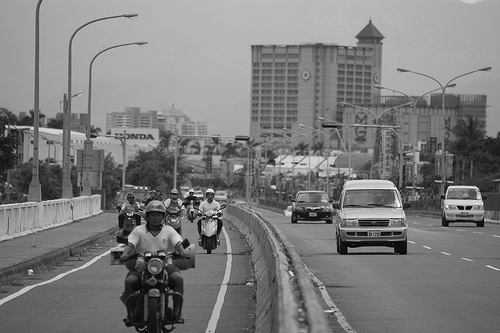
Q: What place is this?
A: It is a street.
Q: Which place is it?
A: It is a street.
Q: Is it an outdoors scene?
A: Yes, it is outdoors.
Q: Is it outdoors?
A: Yes, it is outdoors.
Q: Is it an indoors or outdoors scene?
A: It is outdoors.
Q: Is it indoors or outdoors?
A: It is outdoors.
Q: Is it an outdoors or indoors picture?
A: It is outdoors.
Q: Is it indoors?
A: No, it is outdoors.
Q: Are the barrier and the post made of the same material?
A: No, the barrier is made of cement and the post is made of metal.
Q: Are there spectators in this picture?
A: No, there are no spectators.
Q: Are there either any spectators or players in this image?
A: No, there are no spectators or players.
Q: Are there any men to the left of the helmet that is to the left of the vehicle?
A: Yes, there is a man to the left of the helmet.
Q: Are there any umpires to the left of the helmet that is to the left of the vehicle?
A: No, there is a man to the left of the helmet.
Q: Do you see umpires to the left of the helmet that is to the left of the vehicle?
A: No, there is a man to the left of the helmet.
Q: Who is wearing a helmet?
A: The man is wearing a helmet.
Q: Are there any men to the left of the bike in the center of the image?
A: Yes, there is a man to the left of the bike.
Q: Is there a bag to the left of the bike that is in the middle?
A: No, there is a man to the left of the bike.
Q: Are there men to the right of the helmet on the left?
A: Yes, there is a man to the right of the helmet.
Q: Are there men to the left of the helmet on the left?
A: No, the man is to the right of the helmet.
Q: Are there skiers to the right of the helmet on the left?
A: No, there is a man to the right of the helmet.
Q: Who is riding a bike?
A: The man is riding a bike.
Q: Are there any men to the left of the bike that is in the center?
A: Yes, there is a man to the left of the bike.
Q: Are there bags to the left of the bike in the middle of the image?
A: No, there is a man to the left of the bike.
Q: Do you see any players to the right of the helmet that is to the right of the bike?
A: No, there is a man to the right of the helmet.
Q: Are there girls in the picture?
A: No, there are no girls.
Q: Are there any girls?
A: No, there are no girls.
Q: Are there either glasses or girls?
A: No, there are no girls or glasses.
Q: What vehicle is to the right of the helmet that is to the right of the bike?
A: The vehicle is a car.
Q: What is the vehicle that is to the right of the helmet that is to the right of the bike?
A: The vehicle is a car.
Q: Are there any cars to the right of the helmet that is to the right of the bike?
A: Yes, there is a car to the right of the helmet.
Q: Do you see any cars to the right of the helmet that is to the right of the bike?
A: Yes, there is a car to the right of the helmet.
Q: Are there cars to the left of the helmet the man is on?
A: No, the car is to the right of the helmet.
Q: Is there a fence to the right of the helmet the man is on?
A: No, there is a car to the right of the helmet.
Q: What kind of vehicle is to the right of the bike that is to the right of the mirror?
A: The vehicle is a car.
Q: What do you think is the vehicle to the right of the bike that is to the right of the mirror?
A: The vehicle is a car.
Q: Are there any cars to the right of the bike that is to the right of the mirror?
A: Yes, there is a car to the right of the bike.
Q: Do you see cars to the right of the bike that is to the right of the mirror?
A: Yes, there is a car to the right of the bike.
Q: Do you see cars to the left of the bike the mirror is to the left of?
A: No, the car is to the right of the bike.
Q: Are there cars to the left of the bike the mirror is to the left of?
A: No, the car is to the right of the bike.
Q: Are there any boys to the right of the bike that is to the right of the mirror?
A: No, there is a car to the right of the bike.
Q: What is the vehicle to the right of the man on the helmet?
A: The vehicle is a car.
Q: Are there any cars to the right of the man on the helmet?
A: Yes, there is a car to the right of the man.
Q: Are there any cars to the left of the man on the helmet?
A: No, the car is to the right of the man.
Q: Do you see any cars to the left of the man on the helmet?
A: No, the car is to the right of the man.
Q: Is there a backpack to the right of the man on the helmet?
A: No, there is a car to the right of the man.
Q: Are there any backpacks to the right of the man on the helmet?
A: No, there is a car to the right of the man.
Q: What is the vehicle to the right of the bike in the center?
A: The vehicle is a car.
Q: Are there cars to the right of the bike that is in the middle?
A: Yes, there is a car to the right of the bike.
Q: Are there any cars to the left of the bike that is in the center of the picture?
A: No, the car is to the right of the bike.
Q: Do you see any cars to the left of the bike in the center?
A: No, the car is to the right of the bike.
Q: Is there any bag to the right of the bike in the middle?
A: No, there is a car to the right of the bike.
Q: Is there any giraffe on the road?
A: No, there is a car on the road.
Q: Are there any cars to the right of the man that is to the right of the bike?
A: Yes, there is a car to the right of the man.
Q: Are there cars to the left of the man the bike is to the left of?
A: No, the car is to the right of the man.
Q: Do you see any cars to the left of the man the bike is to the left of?
A: No, the car is to the right of the man.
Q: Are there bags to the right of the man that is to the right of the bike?
A: No, there is a car to the right of the man.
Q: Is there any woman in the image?
A: No, there are no women.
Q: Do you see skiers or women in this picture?
A: No, there are no women or skiers.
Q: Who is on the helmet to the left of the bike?
A: The man is on the helmet.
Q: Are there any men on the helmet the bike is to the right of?
A: Yes, there is a man on the helmet.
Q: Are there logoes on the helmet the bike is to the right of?
A: No, there is a man on the helmet.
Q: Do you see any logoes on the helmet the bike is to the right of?
A: No, there is a man on the helmet.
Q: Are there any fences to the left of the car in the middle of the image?
A: No, there is a man to the left of the car.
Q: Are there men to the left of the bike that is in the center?
A: Yes, there is a man to the left of the bike.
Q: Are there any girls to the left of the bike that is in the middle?
A: No, there is a man to the left of the bike.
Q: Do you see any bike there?
A: Yes, there is a bike.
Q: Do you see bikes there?
A: Yes, there is a bike.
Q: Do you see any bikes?
A: Yes, there is a bike.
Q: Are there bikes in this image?
A: Yes, there is a bike.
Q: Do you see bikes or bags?
A: Yes, there is a bike.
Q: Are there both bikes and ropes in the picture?
A: No, there is a bike but no ropes.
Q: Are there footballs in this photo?
A: No, there are no footballs.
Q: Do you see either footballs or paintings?
A: No, there are no footballs or paintings.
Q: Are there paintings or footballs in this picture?
A: No, there are no footballs or paintings.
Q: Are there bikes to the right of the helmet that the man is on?
A: Yes, there is a bike to the right of the helmet.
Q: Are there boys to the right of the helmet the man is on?
A: No, there is a bike to the right of the helmet.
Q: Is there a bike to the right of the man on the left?
A: Yes, there is a bike to the right of the man.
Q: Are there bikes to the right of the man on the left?
A: Yes, there is a bike to the right of the man.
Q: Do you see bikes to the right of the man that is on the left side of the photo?
A: Yes, there is a bike to the right of the man.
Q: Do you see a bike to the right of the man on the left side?
A: Yes, there is a bike to the right of the man.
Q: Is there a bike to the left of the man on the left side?
A: No, the bike is to the right of the man.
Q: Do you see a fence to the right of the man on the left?
A: No, there is a bike to the right of the man.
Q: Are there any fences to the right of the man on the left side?
A: No, there is a bike to the right of the man.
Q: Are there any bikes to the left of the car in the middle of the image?
A: Yes, there is a bike to the left of the car.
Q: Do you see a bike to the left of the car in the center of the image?
A: Yes, there is a bike to the left of the car.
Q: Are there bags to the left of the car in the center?
A: No, there is a bike to the left of the car.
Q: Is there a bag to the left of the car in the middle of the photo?
A: No, there is a bike to the left of the car.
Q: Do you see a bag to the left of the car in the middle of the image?
A: No, there is a bike to the left of the car.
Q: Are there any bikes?
A: Yes, there is a bike.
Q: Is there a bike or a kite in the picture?
A: Yes, there is a bike.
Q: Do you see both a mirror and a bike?
A: Yes, there are both a bike and a mirror.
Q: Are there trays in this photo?
A: No, there are no trays.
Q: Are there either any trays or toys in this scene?
A: No, there are no trays or toys.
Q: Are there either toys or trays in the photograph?
A: No, there are no trays or toys.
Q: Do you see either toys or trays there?
A: No, there are no trays or toys.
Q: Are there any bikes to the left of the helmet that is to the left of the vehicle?
A: Yes, there is a bike to the left of the helmet.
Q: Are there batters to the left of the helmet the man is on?
A: No, there is a bike to the left of the helmet.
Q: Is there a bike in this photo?
A: Yes, there is a bike.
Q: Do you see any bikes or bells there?
A: Yes, there is a bike.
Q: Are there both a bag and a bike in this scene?
A: No, there is a bike but no bags.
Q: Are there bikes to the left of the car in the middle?
A: Yes, there is a bike to the left of the car.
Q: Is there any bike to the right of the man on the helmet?
A: Yes, there is a bike to the right of the man.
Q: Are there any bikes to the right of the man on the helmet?
A: Yes, there is a bike to the right of the man.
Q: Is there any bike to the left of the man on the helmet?
A: No, the bike is to the right of the man.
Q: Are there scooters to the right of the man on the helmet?
A: No, there is a bike to the right of the man.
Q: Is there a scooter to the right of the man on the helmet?
A: No, there is a bike to the right of the man.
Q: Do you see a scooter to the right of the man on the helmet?
A: No, there is a bike to the right of the man.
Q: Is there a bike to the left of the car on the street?
A: Yes, there is a bike to the left of the car.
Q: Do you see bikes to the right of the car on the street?
A: No, the bike is to the left of the car.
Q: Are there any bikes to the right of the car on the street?
A: No, the bike is to the left of the car.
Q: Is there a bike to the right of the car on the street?
A: No, the bike is to the left of the car.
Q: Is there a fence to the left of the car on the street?
A: No, there is a bike to the left of the car.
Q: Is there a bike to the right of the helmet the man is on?
A: Yes, there is a bike to the right of the helmet.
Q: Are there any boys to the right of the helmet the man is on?
A: No, there is a bike to the right of the helmet.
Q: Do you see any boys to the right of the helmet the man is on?
A: No, there is a bike to the right of the helmet.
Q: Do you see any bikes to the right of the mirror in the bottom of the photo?
A: Yes, there is a bike to the right of the mirror.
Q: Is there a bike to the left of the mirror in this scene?
A: No, the bike is to the right of the mirror.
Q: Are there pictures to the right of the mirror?
A: No, there is a bike to the right of the mirror.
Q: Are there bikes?
A: Yes, there is a bike.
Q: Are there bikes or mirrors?
A: Yes, there is a bike.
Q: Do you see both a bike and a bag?
A: No, there is a bike but no bags.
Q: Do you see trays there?
A: No, there are no trays.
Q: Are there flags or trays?
A: No, there are no trays or flags.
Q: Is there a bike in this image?
A: Yes, there is a bike.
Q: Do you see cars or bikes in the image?
A: Yes, there is a bike.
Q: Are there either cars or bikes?
A: Yes, there is a bike.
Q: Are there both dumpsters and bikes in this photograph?
A: No, there is a bike but no dumpsters.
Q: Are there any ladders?
A: No, there are no ladders.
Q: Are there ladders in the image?
A: No, there are no ladders.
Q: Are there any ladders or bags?
A: No, there are no ladders or bags.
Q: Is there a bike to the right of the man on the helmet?
A: Yes, there is a bike to the right of the man.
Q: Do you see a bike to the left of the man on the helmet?
A: No, the bike is to the right of the man.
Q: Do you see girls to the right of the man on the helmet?
A: No, there is a bike to the right of the man.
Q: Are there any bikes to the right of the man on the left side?
A: Yes, there is a bike to the right of the man.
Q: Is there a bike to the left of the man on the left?
A: No, the bike is to the right of the man.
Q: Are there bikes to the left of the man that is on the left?
A: No, the bike is to the right of the man.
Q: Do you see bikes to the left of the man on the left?
A: No, the bike is to the right of the man.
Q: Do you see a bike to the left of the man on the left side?
A: No, the bike is to the right of the man.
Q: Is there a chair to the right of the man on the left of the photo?
A: No, there is a bike to the right of the man.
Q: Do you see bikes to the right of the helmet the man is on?
A: Yes, there is a bike to the right of the helmet.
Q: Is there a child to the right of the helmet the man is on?
A: No, there is a bike to the right of the helmet.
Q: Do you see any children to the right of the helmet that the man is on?
A: No, there is a bike to the right of the helmet.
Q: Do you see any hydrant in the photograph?
A: No, there are no fire hydrants.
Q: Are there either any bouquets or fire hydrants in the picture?
A: No, there are no fire hydrants or bouquets.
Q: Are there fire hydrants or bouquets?
A: No, there are no fire hydrants or bouquets.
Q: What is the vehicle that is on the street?
A: The vehicle is a car.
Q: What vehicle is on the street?
A: The vehicle is a car.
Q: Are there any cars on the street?
A: Yes, there is a car on the street.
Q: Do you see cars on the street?
A: Yes, there is a car on the street.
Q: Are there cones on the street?
A: No, there is a car on the street.